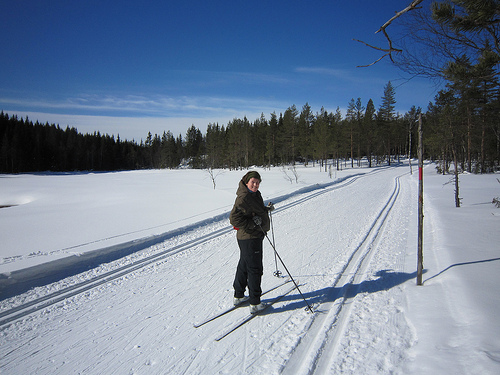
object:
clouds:
[2, 65, 424, 147]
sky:
[2, 1, 497, 146]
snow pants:
[231, 239, 268, 301]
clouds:
[70, 31, 233, 126]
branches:
[352, 24, 498, 79]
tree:
[0, 77, 499, 164]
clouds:
[95, 93, 205, 133]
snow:
[83, 257, 123, 309]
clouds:
[153, 81, 225, 101]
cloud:
[296, 64, 358, 81]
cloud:
[181, 60, 289, 85]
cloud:
[5, 92, 157, 112]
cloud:
[73, 87, 291, 112]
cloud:
[303, 105, 408, 118]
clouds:
[107, 80, 157, 137]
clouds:
[212, 0, 276, 60]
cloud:
[20, 96, 372, 148]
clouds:
[208, 56, 298, 108]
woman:
[215, 166, 288, 317]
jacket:
[203, 186, 288, 242]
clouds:
[271, 39, 348, 93]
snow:
[6, 152, 498, 368]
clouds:
[68, 88, 175, 120]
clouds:
[162, 60, 363, 99]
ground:
[0, 154, 495, 374]